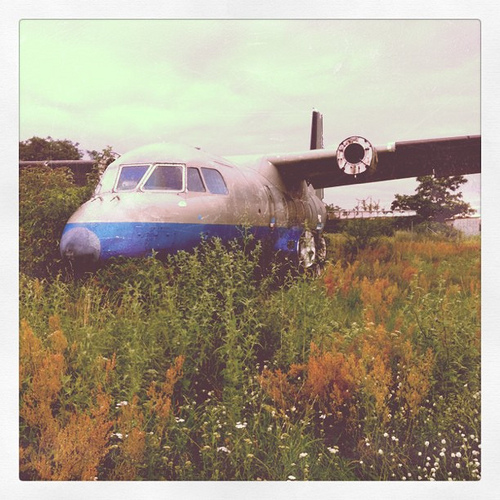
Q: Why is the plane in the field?
A: It's been abandoned.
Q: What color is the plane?
A: White and blue.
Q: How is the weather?
A: Cloudy.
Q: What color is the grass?
A: Green.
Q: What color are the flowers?
A: White.